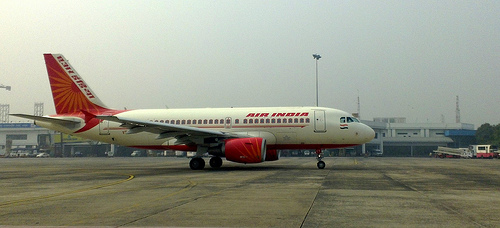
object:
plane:
[10, 52, 377, 170]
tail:
[32, 53, 109, 135]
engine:
[225, 137, 267, 164]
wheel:
[316, 161, 326, 169]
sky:
[1, 0, 499, 123]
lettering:
[245, 112, 310, 117]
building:
[0, 116, 475, 156]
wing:
[95, 115, 253, 145]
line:
[1, 170, 198, 226]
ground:
[0, 158, 500, 227]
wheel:
[189, 157, 205, 170]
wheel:
[209, 156, 223, 168]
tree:
[476, 123, 494, 144]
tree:
[491, 122, 500, 144]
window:
[341, 117, 346, 123]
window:
[347, 117, 354, 123]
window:
[352, 117, 360, 122]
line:
[102, 124, 306, 128]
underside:
[123, 143, 361, 153]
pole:
[314, 57, 319, 106]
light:
[313, 54, 322, 59]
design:
[42, 54, 134, 134]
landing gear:
[315, 147, 325, 169]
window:
[306, 117, 311, 124]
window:
[294, 118, 299, 124]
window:
[282, 117, 288, 124]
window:
[272, 118, 276, 123]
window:
[249, 118, 254, 124]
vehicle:
[9, 147, 31, 158]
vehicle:
[35, 153, 51, 157]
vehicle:
[473, 144, 500, 157]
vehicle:
[431, 145, 476, 159]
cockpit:
[340, 116, 364, 123]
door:
[314, 110, 326, 133]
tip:
[357, 121, 375, 143]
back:
[33, 108, 112, 144]